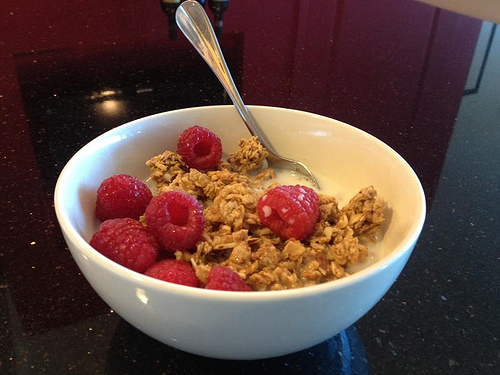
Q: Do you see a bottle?
A: No, there are no bottles.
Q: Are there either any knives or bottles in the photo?
A: No, there are no bottles or knives.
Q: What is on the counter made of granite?
A: The bowl is on the counter.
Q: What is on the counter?
A: The bowl is on the counter.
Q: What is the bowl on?
A: The bowl is on the counter.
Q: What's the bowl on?
A: The bowl is on the counter.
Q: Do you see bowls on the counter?
A: Yes, there is a bowl on the counter.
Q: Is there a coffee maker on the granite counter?
A: No, there is a bowl on the counter.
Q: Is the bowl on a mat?
A: No, the bowl is on the counter.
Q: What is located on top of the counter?
A: The bowl is on top of the counter.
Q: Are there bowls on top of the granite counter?
A: Yes, there is a bowl on top of the counter.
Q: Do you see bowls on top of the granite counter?
A: Yes, there is a bowl on top of the counter.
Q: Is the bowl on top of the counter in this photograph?
A: Yes, the bowl is on top of the counter.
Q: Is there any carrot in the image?
A: No, there are no carrots.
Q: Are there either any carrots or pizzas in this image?
A: No, there are no carrots or pizzas.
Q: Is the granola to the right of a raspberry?
A: Yes, the granola is to the right of a raspberry.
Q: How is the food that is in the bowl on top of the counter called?
A: The food is granola.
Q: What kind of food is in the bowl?
A: The food is granola.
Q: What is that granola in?
A: The granola is in the bowl.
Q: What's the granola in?
A: The granola is in the bowl.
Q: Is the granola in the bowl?
A: Yes, the granola is in the bowl.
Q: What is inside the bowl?
A: The granola is inside the bowl.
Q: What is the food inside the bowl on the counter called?
A: The food is granola.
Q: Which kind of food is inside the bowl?
A: The food is granola.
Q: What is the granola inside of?
A: The granola is inside the bowl.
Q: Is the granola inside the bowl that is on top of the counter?
A: Yes, the granola is inside the bowl.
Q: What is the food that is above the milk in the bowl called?
A: The food is granola.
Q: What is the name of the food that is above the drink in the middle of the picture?
A: The food is granola.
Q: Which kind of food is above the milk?
A: The food is granola.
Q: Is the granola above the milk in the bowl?
A: Yes, the granola is above the milk.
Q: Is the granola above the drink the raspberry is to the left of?
A: Yes, the granola is above the milk.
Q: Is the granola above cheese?
A: No, the granola is above the milk.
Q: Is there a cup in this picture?
A: No, there are no cups.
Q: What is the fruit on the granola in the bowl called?
A: The fruit is a raspberry.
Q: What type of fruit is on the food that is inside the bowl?
A: The fruit is a raspberry.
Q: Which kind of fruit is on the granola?
A: The fruit is a raspberry.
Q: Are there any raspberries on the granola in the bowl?
A: Yes, there is a raspberry on the granola.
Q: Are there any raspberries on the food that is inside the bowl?
A: Yes, there is a raspberry on the granola.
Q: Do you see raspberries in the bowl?
A: Yes, there is a raspberry in the bowl.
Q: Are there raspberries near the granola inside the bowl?
A: Yes, there is a raspberry near the granola.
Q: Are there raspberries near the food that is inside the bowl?
A: Yes, there is a raspberry near the granola.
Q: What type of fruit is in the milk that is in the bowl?
A: The fruit is a raspberry.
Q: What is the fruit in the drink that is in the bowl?
A: The fruit is a raspberry.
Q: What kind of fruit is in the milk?
A: The fruit is a raspberry.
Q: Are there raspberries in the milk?
A: Yes, there is a raspberry in the milk.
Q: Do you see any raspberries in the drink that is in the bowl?
A: Yes, there is a raspberry in the milk.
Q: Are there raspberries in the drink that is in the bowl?
A: Yes, there is a raspberry in the milk.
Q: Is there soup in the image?
A: No, there is no soup.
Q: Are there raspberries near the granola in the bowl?
A: Yes, there is a raspberry near the granola.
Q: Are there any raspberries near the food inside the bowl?
A: Yes, there is a raspberry near the granola.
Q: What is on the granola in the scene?
A: The raspberry is on the granola.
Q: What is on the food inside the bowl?
A: The raspberry is on the granola.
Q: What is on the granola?
A: The raspberry is on the granola.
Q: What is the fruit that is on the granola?
A: The fruit is a raspberry.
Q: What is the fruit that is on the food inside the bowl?
A: The fruit is a raspberry.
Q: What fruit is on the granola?
A: The fruit is a raspberry.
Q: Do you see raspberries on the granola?
A: Yes, there is a raspberry on the granola.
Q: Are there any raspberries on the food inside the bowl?
A: Yes, there is a raspberry on the granola.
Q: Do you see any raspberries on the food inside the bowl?
A: Yes, there is a raspberry on the granola.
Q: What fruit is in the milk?
A: The fruit is a raspberry.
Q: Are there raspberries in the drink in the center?
A: Yes, there is a raspberry in the milk.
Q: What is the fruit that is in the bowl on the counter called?
A: The fruit is a raspberry.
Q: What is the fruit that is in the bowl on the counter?
A: The fruit is a raspberry.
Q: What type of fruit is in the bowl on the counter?
A: The fruit is a raspberry.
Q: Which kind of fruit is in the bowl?
A: The fruit is a raspberry.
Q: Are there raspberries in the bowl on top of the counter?
A: Yes, there is a raspberry in the bowl.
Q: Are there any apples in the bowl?
A: No, there is a raspberry in the bowl.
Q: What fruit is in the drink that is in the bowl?
A: The fruit is a raspberry.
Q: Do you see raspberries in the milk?
A: Yes, there is a raspberry in the milk.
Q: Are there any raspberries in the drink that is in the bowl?
A: Yes, there is a raspberry in the milk.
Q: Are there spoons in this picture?
A: Yes, there is a spoon.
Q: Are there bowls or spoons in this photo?
A: Yes, there is a spoon.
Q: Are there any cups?
A: No, there are no cups.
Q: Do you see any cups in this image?
A: No, there are no cups.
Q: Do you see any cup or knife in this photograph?
A: No, there are no cups or knives.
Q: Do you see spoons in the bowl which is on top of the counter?
A: Yes, there is a spoon in the bowl.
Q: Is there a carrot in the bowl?
A: No, there is a spoon in the bowl.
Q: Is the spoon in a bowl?
A: Yes, the spoon is in a bowl.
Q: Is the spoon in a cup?
A: No, the spoon is in a bowl.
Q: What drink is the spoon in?
A: The spoon is in the milk.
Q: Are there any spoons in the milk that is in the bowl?
A: Yes, there is a spoon in the milk.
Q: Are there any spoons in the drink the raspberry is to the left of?
A: Yes, there is a spoon in the milk.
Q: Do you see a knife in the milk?
A: No, there is a spoon in the milk.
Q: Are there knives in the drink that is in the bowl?
A: No, there is a spoon in the milk.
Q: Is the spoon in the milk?
A: Yes, the spoon is in the milk.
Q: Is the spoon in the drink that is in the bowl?
A: Yes, the spoon is in the milk.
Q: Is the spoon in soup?
A: No, the spoon is in the milk.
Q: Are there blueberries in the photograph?
A: No, there are no blueberries.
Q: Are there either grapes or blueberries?
A: No, there are no blueberries or grapes.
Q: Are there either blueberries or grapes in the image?
A: No, there are no blueberries or grapes.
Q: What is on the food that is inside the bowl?
A: The raspberry is on the granola.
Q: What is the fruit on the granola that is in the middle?
A: The fruit is a raspberry.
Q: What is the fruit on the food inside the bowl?
A: The fruit is a raspberry.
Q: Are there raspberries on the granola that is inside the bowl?
A: Yes, there is a raspberry on the granola.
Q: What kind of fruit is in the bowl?
A: The fruit is a raspberry.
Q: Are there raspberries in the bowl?
A: Yes, there is a raspberry in the bowl.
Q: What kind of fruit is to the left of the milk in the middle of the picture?
A: The fruit is a raspberry.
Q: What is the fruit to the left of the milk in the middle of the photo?
A: The fruit is a raspberry.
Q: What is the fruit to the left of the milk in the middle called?
A: The fruit is a raspberry.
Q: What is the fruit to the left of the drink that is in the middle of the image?
A: The fruit is a raspberry.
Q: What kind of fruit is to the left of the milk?
A: The fruit is a raspberry.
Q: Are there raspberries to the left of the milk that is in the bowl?
A: Yes, there is a raspberry to the left of the milk.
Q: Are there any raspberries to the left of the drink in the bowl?
A: Yes, there is a raspberry to the left of the milk.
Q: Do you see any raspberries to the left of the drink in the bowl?
A: Yes, there is a raspberry to the left of the milk.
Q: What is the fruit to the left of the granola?
A: The fruit is a raspberry.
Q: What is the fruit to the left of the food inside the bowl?
A: The fruit is a raspberry.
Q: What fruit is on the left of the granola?
A: The fruit is a raspberry.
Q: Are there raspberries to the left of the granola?
A: Yes, there is a raspberry to the left of the granola.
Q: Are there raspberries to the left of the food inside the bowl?
A: Yes, there is a raspberry to the left of the granola.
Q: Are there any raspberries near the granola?
A: Yes, there is a raspberry near the granola.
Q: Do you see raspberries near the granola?
A: Yes, there is a raspberry near the granola.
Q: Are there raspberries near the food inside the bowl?
A: Yes, there is a raspberry near the granola.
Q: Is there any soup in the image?
A: No, there is no soup.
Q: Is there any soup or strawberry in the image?
A: No, there are no soup or strawberries.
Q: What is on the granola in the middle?
A: The raspberry is on the granola.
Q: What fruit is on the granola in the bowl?
A: The fruit is a raspberry.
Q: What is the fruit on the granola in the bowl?
A: The fruit is a raspberry.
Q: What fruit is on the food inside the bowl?
A: The fruit is a raspberry.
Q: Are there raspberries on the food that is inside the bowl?
A: Yes, there is a raspberry on the granola.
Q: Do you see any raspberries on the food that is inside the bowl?
A: Yes, there is a raspberry on the granola.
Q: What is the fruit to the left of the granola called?
A: The fruit is a raspberry.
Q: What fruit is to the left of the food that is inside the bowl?
A: The fruit is a raspberry.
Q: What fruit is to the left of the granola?
A: The fruit is a raspberry.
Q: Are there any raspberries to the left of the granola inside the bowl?
A: Yes, there is a raspberry to the left of the granola.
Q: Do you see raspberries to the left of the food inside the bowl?
A: Yes, there is a raspberry to the left of the granola.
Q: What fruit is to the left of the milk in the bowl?
A: The fruit is a raspberry.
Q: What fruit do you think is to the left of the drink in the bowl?
A: The fruit is a raspberry.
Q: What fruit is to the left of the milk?
A: The fruit is a raspberry.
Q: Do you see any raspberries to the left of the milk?
A: Yes, there is a raspberry to the left of the milk.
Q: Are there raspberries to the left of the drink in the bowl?
A: Yes, there is a raspberry to the left of the milk.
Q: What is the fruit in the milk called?
A: The fruit is a raspberry.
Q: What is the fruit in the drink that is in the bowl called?
A: The fruit is a raspberry.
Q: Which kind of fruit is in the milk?
A: The fruit is a raspberry.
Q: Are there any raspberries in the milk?
A: Yes, there is a raspberry in the milk.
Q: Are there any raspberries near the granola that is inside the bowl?
A: Yes, there is a raspberry near the granola.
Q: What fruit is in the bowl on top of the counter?
A: The fruit is a raspberry.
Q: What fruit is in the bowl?
A: The fruit is a raspberry.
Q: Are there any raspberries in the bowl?
A: Yes, there is a raspberry in the bowl.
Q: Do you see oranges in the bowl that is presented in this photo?
A: No, there is a raspberry in the bowl.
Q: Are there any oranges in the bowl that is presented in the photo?
A: No, there is a raspberry in the bowl.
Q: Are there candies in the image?
A: No, there are no candies.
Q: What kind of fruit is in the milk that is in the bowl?
A: The fruit is a raspberry.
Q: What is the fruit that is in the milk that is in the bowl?
A: The fruit is a raspberry.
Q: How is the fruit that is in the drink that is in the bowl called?
A: The fruit is a raspberry.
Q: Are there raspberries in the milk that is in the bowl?
A: Yes, there is a raspberry in the milk.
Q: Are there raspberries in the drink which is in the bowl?
A: Yes, there is a raspberry in the milk.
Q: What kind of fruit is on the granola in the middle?
A: The fruit is a raspberry.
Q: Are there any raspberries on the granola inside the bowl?
A: Yes, there is a raspberry on the granola.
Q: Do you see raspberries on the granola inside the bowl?
A: Yes, there is a raspberry on the granola.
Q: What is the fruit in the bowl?
A: The fruit is a raspberry.